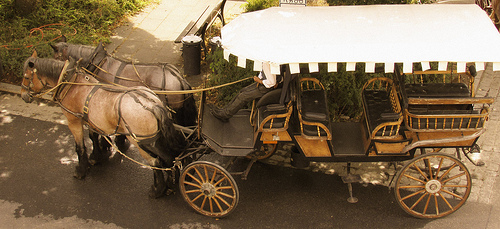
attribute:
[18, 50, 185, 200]
horse — tan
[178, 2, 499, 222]
wagon — horse drawn, pulled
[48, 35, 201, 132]
horse — tan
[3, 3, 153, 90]
foliage — green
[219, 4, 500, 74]
canopy — white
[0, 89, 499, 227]
road — dark grey, wet, paved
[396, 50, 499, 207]
walkway — stone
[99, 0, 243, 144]
walkway — wooden, white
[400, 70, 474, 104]
back seat — brown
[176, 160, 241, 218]
left wheel — wooden, brown, round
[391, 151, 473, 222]
left wheel — wooden, brown, round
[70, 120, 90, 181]
leg — black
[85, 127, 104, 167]
leg — black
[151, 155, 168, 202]
leg — black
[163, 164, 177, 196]
leg — black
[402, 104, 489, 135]
back seat — brown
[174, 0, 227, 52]
bench — wooden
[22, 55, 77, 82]
mane — brown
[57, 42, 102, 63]
mane — brown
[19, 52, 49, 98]
bridle — brown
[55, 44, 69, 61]
bridle — brown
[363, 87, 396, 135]
seat — brown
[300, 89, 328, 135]
seat — brown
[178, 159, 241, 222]
tire — round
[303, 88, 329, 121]
cushion — black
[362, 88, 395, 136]
cushion — black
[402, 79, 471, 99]
cushion — black